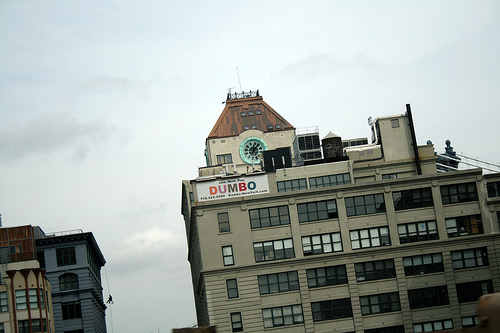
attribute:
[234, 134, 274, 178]
window — green, round